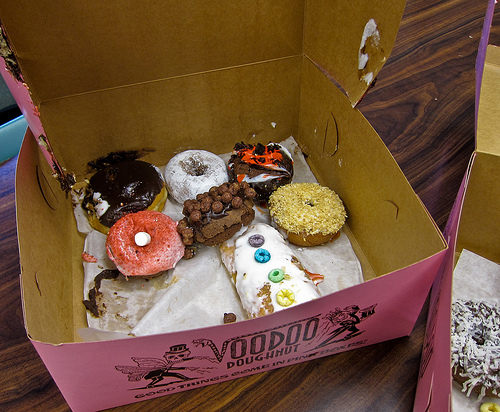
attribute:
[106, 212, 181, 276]
donut — pink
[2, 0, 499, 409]
table — brown, wooden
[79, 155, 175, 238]
donut — chocolate, glazed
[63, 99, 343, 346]
donut — white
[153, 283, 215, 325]
napkin — white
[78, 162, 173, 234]
doughnut — brown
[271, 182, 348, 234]
icing — yellow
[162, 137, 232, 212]
donut — round, powdered, sugar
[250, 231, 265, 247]
froot loop — purple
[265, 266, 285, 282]
froot loop — green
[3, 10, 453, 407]
box — pink, cardboard, brown, doughnut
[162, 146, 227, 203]
doughnut — white, powdered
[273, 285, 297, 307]
froot loop — yellow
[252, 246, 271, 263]
froot loop — blue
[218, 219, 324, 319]
donut — white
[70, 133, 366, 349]
paper — white